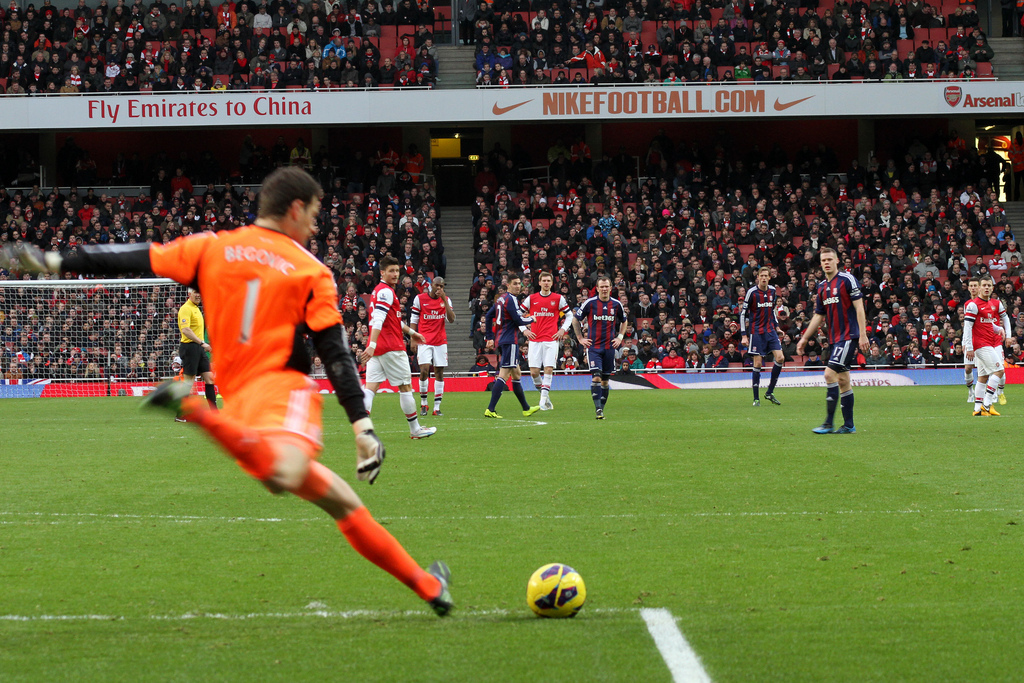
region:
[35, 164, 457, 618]
Soccer player in orange uniform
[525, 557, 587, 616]
Yellow and blue soccer ball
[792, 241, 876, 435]
Soccer player in maroon and black uniform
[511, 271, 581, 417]
Soccer player in red and white uniform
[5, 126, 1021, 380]
Lower tier of stand full of spectators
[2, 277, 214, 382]
White net in front of crowd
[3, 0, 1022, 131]
Upper tier of stands full of spectators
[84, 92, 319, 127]
Advertisement reading "Fly Emirates to China"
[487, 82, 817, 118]
Advertisement for Nike football website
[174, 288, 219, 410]
Man in yellow shirt and black pants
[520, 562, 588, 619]
yellow soccer ball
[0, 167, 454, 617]
soccer player about to kick a ball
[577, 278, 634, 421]
soccer player trying to black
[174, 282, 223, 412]
soccer player in yellow jersey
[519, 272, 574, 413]
soccer player in red jersey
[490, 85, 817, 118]
orange billboard for Nike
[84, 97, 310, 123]
billboard for emirates airlines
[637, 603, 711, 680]
white line on the field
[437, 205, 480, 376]
stairwell in the stadium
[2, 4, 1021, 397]
bleachers in the stadium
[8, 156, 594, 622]
Goalie kicking soccer ball.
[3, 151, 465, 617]
Goalie wearing orange uniform.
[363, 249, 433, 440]
Man wearing red jersey.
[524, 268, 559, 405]
Athlete wearing white shorts.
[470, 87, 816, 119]
Banner ad on stadium railing.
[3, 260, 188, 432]
Soccer goal on field.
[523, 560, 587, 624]
Soccer ball on field.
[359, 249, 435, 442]
Man walks on field.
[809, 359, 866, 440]
Athlete wearing soccer cleats.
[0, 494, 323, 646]
White chalk lines on soccer field.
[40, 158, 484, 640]
a person walking on the grass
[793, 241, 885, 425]
a person walking on the grass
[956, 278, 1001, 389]
a person walking on the grass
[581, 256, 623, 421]
a person walking on the grass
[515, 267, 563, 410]
a person walking on the grass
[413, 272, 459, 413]
a person walking on the grass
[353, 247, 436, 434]
a person walking on the grass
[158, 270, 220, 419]
a person walking on the grass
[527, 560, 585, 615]
yellow and black soccer ball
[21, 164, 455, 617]
soccer player in bright orange uniform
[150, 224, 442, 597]
bright orange soccer uniform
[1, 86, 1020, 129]
white advertising sign with red writing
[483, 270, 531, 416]
soccer player in red and black uniform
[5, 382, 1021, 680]
green grass on a soccer field